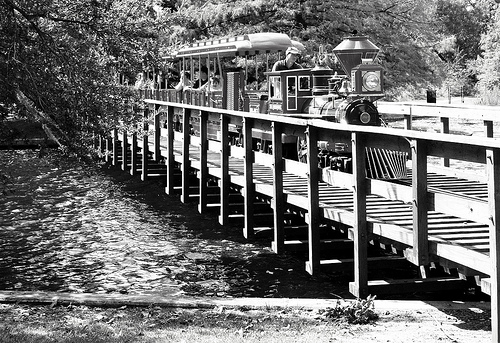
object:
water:
[33, 194, 193, 279]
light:
[361, 70, 380, 91]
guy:
[272, 46, 305, 73]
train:
[95, 32, 412, 181]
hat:
[286, 46, 302, 55]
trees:
[318, 0, 498, 70]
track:
[170, 116, 500, 232]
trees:
[0, 0, 167, 160]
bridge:
[80, 92, 499, 300]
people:
[191, 66, 209, 90]